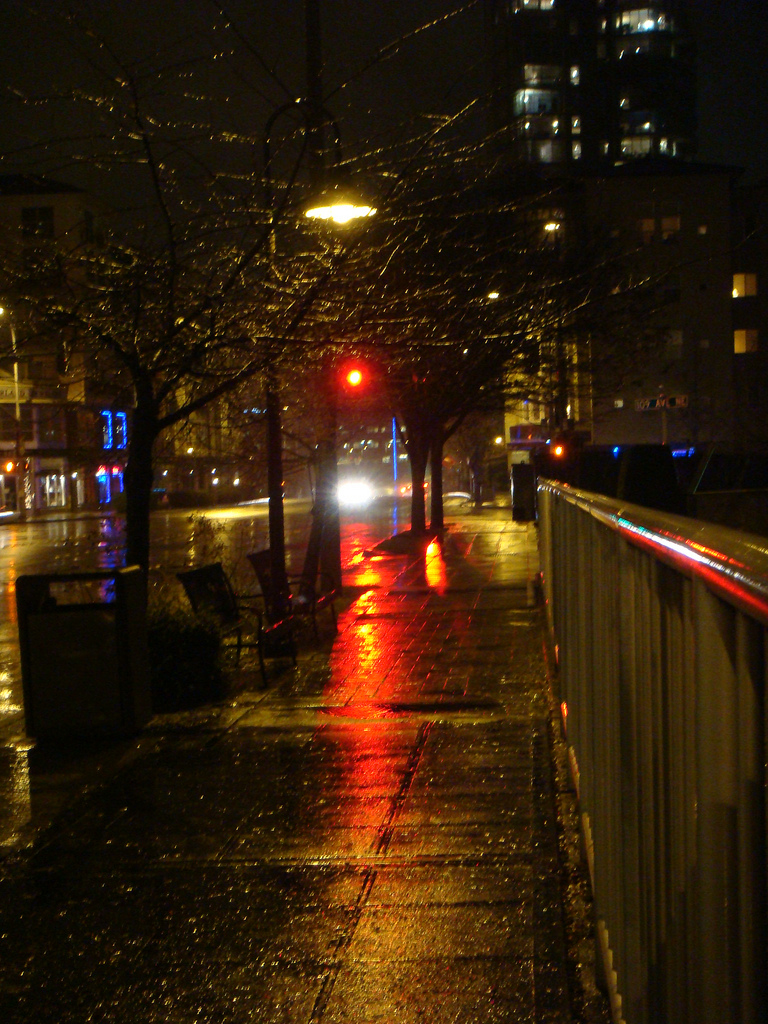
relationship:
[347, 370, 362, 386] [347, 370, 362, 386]
light of light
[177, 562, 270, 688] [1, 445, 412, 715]
bench on street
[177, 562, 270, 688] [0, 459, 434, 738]
bench on street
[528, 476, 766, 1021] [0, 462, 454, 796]
fence on street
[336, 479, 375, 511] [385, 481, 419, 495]
headlights of car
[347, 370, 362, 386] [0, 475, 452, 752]
light over street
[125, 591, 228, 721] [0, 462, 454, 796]
bush by street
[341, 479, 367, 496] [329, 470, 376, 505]
headlights of car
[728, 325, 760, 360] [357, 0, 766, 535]
window on building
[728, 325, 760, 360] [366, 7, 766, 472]
window on building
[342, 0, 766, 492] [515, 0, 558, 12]
building with window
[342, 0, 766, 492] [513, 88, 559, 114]
building with window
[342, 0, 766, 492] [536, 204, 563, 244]
building with window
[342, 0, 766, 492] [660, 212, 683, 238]
building with window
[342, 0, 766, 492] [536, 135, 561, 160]
building with window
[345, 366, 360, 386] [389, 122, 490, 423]
light between tree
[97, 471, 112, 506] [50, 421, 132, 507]
blue sign between window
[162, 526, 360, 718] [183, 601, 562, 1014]
bench on a side walk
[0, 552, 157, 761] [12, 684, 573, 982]
garbage can near side walk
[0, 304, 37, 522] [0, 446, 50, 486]
streetlamp with sign